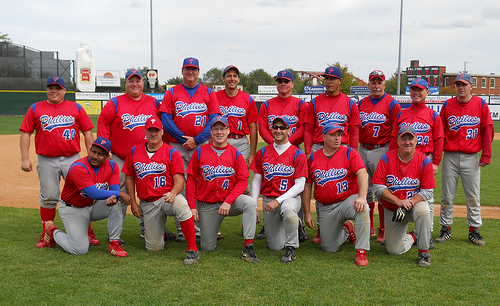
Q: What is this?
A: A team.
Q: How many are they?
A: Fifteen.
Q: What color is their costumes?
A: Red.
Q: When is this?
A: Daytime.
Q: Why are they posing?
A: Photo.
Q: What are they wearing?
A: Caps.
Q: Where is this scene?
A: At a ball park.